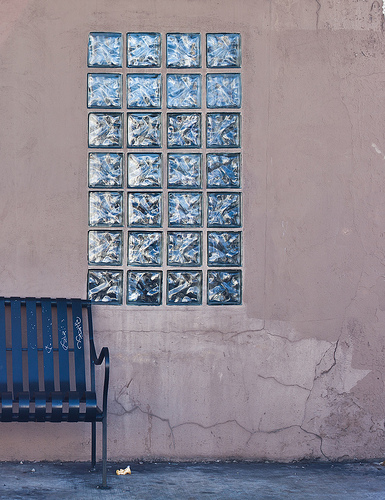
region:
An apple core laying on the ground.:
[114, 462, 150, 483]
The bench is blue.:
[3, 292, 155, 486]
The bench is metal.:
[2, 292, 115, 495]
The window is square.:
[87, 25, 126, 68]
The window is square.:
[125, 29, 162, 71]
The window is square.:
[166, 31, 202, 70]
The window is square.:
[204, 30, 250, 69]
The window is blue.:
[83, 26, 125, 72]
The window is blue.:
[126, 29, 160, 66]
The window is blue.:
[163, 29, 202, 72]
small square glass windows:
[83, 28, 246, 309]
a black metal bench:
[0, 293, 113, 489]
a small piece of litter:
[115, 465, 131, 476]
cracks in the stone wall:
[111, 317, 377, 464]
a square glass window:
[206, 269, 245, 308]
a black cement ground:
[0, 458, 383, 499]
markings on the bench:
[32, 304, 84, 352]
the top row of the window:
[84, 28, 245, 70]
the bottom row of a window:
[80, 266, 248, 308]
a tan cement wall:
[256, 1, 384, 460]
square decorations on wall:
[77, 24, 248, 316]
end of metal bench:
[2, 287, 121, 493]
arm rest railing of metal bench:
[78, 298, 118, 425]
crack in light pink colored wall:
[112, 383, 361, 462]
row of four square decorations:
[81, 225, 247, 271]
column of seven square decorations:
[199, 26, 249, 310]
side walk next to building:
[2, 455, 383, 498]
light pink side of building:
[3, 3, 382, 464]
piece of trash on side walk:
[109, 460, 136, 483]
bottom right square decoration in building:
[203, 266, 245, 308]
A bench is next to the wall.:
[0, 0, 382, 496]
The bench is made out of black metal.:
[0, 294, 113, 488]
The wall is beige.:
[263, 110, 377, 307]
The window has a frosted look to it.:
[84, 27, 242, 307]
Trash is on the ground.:
[112, 463, 129, 475]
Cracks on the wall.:
[308, 330, 353, 387]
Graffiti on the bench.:
[35, 310, 82, 354]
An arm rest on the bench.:
[88, 341, 112, 411]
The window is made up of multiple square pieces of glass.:
[84, 30, 242, 307]